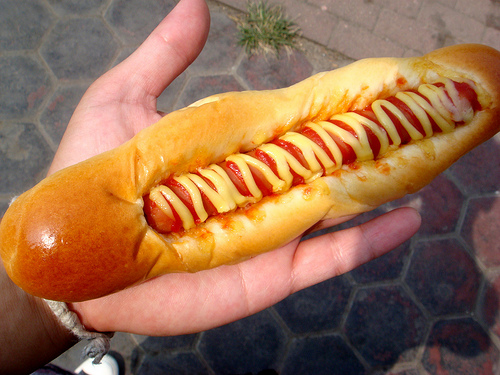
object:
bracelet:
[42, 299, 114, 369]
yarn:
[227, 157, 261, 197]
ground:
[2, 2, 499, 375]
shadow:
[127, 136, 499, 374]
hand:
[28, 0, 421, 338]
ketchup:
[226, 161, 238, 174]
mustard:
[146, 77, 461, 229]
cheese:
[157, 184, 196, 232]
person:
[0, 0, 427, 374]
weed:
[227, 0, 312, 63]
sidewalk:
[212, 2, 499, 106]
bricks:
[341, 285, 428, 372]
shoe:
[67, 351, 124, 375]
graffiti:
[430, 260, 462, 313]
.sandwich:
[0, 42, 499, 303]